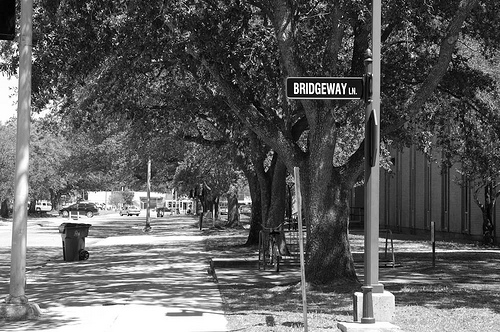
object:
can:
[59, 221, 90, 261]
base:
[0, 296, 40, 321]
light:
[1, 1, 44, 324]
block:
[354, 290, 395, 324]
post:
[364, 0, 384, 294]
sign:
[286, 77, 367, 98]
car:
[119, 204, 140, 217]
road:
[1, 215, 197, 328]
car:
[56, 202, 101, 219]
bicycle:
[259, 222, 285, 273]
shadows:
[164, 309, 223, 318]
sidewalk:
[1, 214, 233, 331]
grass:
[226, 267, 499, 331]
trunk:
[298, 178, 362, 294]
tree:
[2, 2, 499, 293]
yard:
[205, 225, 499, 331]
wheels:
[80, 250, 89, 260]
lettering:
[288, 81, 356, 94]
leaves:
[8, 87, 12, 90]